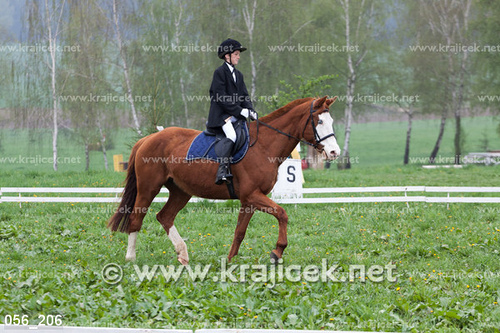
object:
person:
[205, 37, 257, 185]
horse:
[105, 95, 343, 267]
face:
[304, 112, 341, 161]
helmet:
[217, 38, 248, 60]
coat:
[205, 61, 259, 136]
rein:
[249, 115, 314, 148]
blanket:
[186, 121, 250, 162]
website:
[99, 257, 401, 286]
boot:
[214, 137, 237, 185]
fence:
[2, 185, 499, 208]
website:
[267, 43, 360, 53]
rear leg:
[156, 192, 192, 265]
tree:
[335, 0, 370, 171]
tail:
[104, 134, 152, 234]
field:
[0, 203, 498, 331]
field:
[2, 114, 500, 185]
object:
[112, 154, 123, 173]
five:
[12, 314, 21, 325]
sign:
[272, 158, 304, 199]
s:
[286, 164, 297, 184]